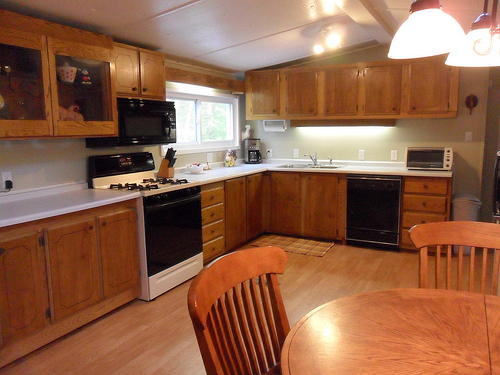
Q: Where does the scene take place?
A: In a kitchen.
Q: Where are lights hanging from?
A: The ceiling.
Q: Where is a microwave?
A: Above the stove.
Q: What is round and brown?
A: Table.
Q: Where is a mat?
A: On the floor.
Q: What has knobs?
A: Drawers.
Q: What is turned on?
A: Lights.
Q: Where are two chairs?
A: Around the table.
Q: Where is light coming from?
A: A window.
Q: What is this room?
A: Kitchen.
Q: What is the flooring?
A: Wood.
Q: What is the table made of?
A: Wood.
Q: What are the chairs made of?
A: Wood.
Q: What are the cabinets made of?
A: Wood.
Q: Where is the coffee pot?
A: In the corner of the counter.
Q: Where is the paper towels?
A: Hanging from the counter.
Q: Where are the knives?
A: On the counter by the stove.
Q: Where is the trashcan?
A: The end of the cabinet.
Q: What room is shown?
A: Kitchen.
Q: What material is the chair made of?
A: Wood.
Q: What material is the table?
A: Wood.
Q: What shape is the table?
A: Round.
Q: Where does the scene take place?
A: In a kitchen.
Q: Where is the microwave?
A: Above the stove.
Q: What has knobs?
A: Drawers.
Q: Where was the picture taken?
A: In a kitchen.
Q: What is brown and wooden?
A: The floor.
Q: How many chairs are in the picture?
A: Two.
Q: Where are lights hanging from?
A: The ceiling.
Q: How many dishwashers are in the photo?
A: One.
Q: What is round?
A: The table.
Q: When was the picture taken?
A: Daytime.